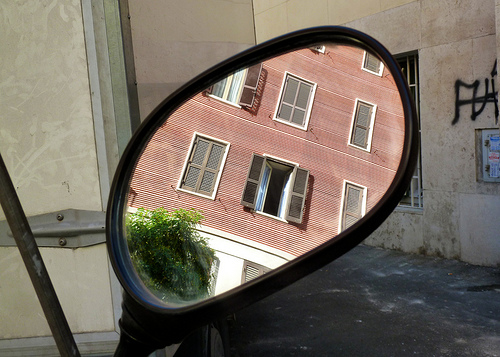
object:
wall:
[251, 0, 500, 268]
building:
[0, 0, 500, 357]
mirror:
[102, 23, 416, 316]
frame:
[100, 23, 420, 320]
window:
[238, 151, 311, 225]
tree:
[123, 207, 218, 303]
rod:
[0, 152, 82, 357]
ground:
[218, 240, 500, 357]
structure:
[126, 0, 499, 268]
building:
[123, 43, 407, 296]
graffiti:
[450, 57, 500, 128]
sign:
[487, 134, 499, 178]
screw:
[56, 213, 65, 222]